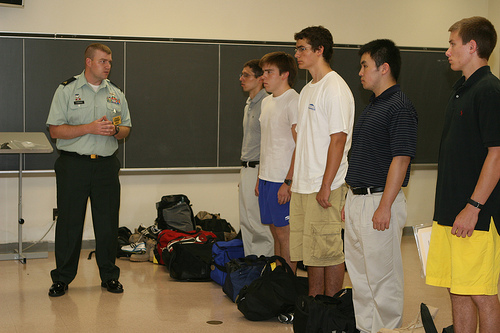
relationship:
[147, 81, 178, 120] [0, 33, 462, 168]
portion of chalkboard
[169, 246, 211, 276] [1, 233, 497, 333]
duffle bag on floor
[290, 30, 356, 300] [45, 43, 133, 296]
man standing by officer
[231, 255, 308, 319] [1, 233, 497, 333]
bag on floor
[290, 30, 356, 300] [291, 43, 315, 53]
man has glasses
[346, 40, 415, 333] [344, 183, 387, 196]
person wearing belt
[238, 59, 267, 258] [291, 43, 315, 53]
man wearing glasses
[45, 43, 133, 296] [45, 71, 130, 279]
officer in uniform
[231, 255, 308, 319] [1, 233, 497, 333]
bag on ground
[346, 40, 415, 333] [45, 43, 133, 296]
person standing in front of officer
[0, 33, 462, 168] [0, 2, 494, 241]
chalkboard on wall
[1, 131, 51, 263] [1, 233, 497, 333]
table on floor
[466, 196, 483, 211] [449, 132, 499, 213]
watch on arm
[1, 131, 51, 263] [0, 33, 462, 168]
podium next to chalkboard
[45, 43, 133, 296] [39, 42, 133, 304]
officer wearing uniform